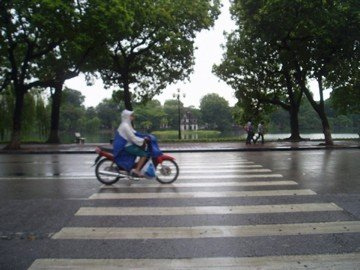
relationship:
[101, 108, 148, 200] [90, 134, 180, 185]
person riding bicycle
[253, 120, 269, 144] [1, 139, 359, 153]
people on sidewalk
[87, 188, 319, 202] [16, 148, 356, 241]
stripe on street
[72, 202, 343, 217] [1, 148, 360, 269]
line in road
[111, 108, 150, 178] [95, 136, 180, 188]
person on a motorcycle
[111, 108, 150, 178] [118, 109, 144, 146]
person wearing hoodie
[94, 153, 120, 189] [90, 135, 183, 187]
wheel on motorcycle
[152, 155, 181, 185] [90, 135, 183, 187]
wheel on motorcycle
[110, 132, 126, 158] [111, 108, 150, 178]
blue tarp on person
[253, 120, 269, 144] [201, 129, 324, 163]
people walking on street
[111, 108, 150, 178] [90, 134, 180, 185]
person riding bicycle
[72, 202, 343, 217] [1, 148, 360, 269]
line on road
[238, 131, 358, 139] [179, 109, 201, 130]
pond in front of house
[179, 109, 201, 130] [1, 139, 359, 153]
house next to sidewalk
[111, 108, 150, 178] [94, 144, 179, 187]
person riding skooter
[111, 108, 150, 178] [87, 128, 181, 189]
person riding motorcycle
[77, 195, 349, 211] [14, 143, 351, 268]
stripe on street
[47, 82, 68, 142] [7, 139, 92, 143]
tree trunk on grass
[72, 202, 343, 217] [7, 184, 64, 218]
line on road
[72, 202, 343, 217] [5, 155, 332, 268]
line on road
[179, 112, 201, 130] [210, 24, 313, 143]
house beyond tree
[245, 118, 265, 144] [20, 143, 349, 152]
people walking on sidewalk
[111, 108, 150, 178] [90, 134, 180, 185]
person on bicycle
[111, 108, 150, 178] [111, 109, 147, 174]
person with rain parka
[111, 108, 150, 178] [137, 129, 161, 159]
person with tarp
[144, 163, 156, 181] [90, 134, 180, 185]
bag hanging from bicycle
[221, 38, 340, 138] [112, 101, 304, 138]
tree outlines sidewalk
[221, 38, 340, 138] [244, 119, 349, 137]
tree outlines pond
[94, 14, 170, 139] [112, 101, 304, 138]
tree outlines sidewalk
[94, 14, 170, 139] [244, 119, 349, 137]
tree outlines pond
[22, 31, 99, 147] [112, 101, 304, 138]
tree outlines sidewalk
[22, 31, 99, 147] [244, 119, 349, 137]
tree outlines pond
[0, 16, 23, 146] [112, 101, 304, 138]
tree outlines sidewalk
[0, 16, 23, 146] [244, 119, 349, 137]
tree outlines pond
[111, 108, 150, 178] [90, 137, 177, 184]
person rides bicycle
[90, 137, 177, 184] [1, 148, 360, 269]
bicycle in road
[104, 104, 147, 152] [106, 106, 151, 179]
rain parka on person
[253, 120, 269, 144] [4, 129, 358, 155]
people walk on sidewalk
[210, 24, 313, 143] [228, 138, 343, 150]
tree on sidewalk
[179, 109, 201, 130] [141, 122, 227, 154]
house in field